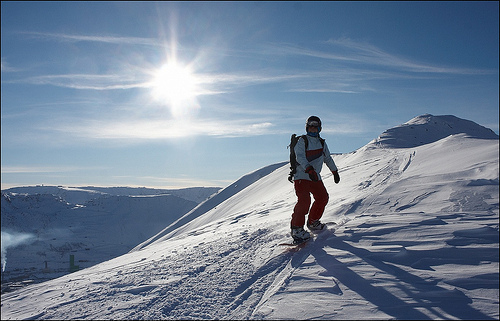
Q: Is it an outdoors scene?
A: Yes, it is outdoors.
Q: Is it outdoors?
A: Yes, it is outdoors.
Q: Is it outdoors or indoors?
A: It is outdoors.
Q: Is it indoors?
A: No, it is outdoors.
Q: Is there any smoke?
A: Yes, there is smoke.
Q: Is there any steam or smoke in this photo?
A: Yes, there is smoke.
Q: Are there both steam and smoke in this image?
A: No, there is smoke but no steam.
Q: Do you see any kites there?
A: No, there are no kites.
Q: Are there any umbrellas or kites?
A: No, there are no kites or umbrellas.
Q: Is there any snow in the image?
A: Yes, there is snow.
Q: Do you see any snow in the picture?
A: Yes, there is snow.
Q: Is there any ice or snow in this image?
A: Yes, there is snow.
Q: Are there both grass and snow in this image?
A: No, there is snow but no grass.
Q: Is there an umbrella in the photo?
A: No, there are no umbrellas.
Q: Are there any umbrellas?
A: No, there are no umbrellas.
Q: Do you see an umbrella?
A: No, there are no umbrellas.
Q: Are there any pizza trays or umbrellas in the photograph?
A: No, there are no umbrellas or pizza trays.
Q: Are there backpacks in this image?
A: Yes, there is a backpack.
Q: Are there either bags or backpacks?
A: Yes, there is a backpack.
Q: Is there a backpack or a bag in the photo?
A: Yes, there is a backpack.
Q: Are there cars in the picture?
A: No, there are no cars.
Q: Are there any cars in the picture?
A: No, there are no cars.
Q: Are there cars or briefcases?
A: No, there are no cars or briefcases.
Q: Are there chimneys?
A: No, there are no chimneys.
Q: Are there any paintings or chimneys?
A: No, there are no chimneys or paintings.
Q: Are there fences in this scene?
A: No, there are no fences.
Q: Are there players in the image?
A: No, there are no players.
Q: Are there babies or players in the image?
A: No, there are no players or babies.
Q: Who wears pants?
A: The man wears pants.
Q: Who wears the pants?
A: The man wears pants.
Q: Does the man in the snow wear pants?
A: Yes, the man wears pants.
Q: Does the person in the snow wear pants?
A: Yes, the man wears pants.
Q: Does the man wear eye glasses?
A: No, the man wears pants.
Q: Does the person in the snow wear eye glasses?
A: No, the man wears pants.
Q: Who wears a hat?
A: The man wears a hat.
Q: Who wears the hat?
A: The man wears a hat.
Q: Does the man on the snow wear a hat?
A: Yes, the man wears a hat.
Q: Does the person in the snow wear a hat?
A: Yes, the man wears a hat.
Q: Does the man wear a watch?
A: No, the man wears a hat.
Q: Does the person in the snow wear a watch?
A: No, the man wears a hat.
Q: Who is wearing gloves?
A: The man is wearing gloves.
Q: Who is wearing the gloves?
A: The man is wearing gloves.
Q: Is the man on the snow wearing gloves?
A: Yes, the man is wearing gloves.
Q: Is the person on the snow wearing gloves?
A: Yes, the man is wearing gloves.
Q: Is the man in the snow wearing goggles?
A: No, the man is wearing gloves.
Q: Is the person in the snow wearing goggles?
A: No, the man is wearing gloves.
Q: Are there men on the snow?
A: Yes, there is a man on the snow.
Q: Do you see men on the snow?
A: Yes, there is a man on the snow.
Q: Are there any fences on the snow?
A: No, there is a man on the snow.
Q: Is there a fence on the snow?
A: No, there is a man on the snow.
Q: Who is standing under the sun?
A: The man is standing under the sun.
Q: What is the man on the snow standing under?
A: The man is standing under the sun.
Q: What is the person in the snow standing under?
A: The man is standing under the sun.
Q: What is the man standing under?
A: The man is standing under the sun.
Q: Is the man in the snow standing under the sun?
A: Yes, the man is standing under the sun.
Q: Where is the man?
A: The man is in the snow.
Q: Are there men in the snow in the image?
A: Yes, there is a man in the snow.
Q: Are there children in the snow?
A: No, there is a man in the snow.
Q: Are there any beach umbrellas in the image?
A: No, there are no beach umbrellas.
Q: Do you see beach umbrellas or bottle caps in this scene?
A: No, there are no beach umbrellas or bottle caps.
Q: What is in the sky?
A: The clouds are in the sky.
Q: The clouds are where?
A: The clouds are in the sky.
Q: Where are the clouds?
A: The clouds are in the sky.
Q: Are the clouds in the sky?
A: Yes, the clouds are in the sky.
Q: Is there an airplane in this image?
A: No, there are no airplanes.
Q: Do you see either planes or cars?
A: No, there are no planes or cars.